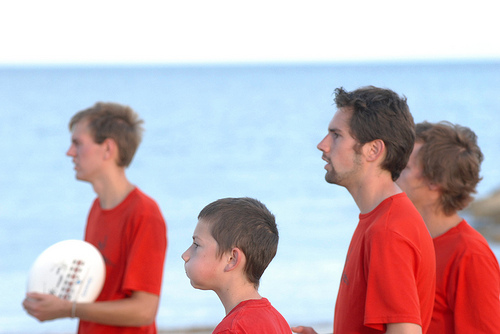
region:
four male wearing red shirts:
[21, 90, 493, 332]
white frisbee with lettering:
[24, 235, 104, 304]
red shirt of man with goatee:
[339, 189, 436, 332]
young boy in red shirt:
[172, 189, 294, 333]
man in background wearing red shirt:
[38, 100, 175, 331]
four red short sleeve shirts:
[55, 201, 491, 333]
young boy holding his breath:
[179, 196, 306, 333]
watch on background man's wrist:
[63, 295, 81, 322]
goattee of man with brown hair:
[320, 153, 344, 179]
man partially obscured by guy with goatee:
[399, 115, 499, 330]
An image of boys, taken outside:
[0, 55, 499, 325]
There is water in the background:
[150, 72, 315, 174]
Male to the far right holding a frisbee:
[27, 99, 174, 329]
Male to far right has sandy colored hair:
[63, 103, 142, 139]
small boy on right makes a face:
[180, 195, 285, 330]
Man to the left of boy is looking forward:
[310, 80, 425, 325]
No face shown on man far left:
[415, 115, 495, 325]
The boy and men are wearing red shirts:
[329, 193, 434, 330]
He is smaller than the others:
[176, 199, 291, 330]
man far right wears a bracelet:
[63, 298, 83, 318]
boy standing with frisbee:
[48, 103, 174, 324]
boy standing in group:
[177, 187, 291, 332]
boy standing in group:
[322, 78, 398, 331]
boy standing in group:
[418, 107, 488, 332]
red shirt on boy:
[330, 203, 418, 326]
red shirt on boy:
[433, 222, 482, 332]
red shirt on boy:
[76, 200, 170, 315]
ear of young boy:
[223, 249, 246, 274]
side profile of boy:
[174, 222, 231, 292]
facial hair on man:
[321, 157, 349, 188]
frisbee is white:
[33, 230, 126, 307]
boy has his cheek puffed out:
[173, 243, 230, 287]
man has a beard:
[320, 148, 380, 189]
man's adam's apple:
[89, 178, 116, 196]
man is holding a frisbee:
[42, 220, 142, 327]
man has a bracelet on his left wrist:
[58, 290, 89, 324]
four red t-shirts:
[96, 203, 498, 329]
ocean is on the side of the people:
[162, 97, 313, 164]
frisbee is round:
[27, 230, 112, 332]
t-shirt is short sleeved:
[126, 261, 168, 325]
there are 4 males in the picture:
[12, 92, 487, 326]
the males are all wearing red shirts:
[19, 83, 487, 320]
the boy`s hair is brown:
[165, 174, 296, 331]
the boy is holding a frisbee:
[15, 92, 170, 319]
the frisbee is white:
[15, 223, 107, 327]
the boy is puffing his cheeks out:
[157, 202, 237, 302]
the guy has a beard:
[285, 115, 377, 193]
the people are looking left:
[27, 80, 479, 275]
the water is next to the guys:
[42, 80, 316, 220]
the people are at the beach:
[22, 82, 478, 308]